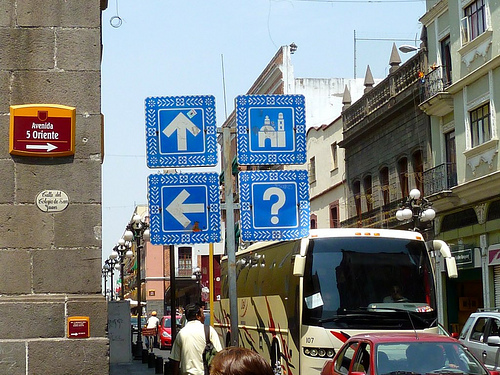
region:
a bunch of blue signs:
[142, 91, 317, 242]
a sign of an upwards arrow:
[142, 96, 224, 174]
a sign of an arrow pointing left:
[141, 171, 222, 245]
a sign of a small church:
[228, 105, 315, 170]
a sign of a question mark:
[237, 178, 308, 243]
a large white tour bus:
[220, 233, 444, 364]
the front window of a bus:
[327, 231, 447, 336]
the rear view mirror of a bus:
[425, 239, 465, 284]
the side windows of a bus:
[234, 251, 286, 293]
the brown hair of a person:
[201, 351, 268, 371]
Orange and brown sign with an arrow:
[7, 101, 78, 164]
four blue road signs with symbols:
[139, 93, 309, 250]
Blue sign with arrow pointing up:
[140, 93, 220, 170]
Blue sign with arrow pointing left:
[144, 171, 222, 246]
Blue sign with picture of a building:
[233, 93, 310, 169]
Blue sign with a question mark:
[235, 167, 310, 242]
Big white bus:
[215, 222, 449, 374]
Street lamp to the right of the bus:
[387, 183, 439, 232]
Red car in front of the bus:
[313, 318, 490, 374]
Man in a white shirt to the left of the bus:
[161, 296, 221, 373]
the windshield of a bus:
[304, 235, 441, 334]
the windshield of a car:
[374, 336, 481, 373]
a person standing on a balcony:
[410, 63, 453, 98]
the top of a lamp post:
[390, 186, 440, 226]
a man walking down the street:
[162, 302, 227, 374]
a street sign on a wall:
[3, 99, 83, 166]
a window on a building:
[462, 102, 496, 151]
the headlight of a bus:
[300, 344, 338, 364]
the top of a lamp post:
[123, 212, 153, 251]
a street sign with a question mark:
[235, 167, 313, 245]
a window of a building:
[467, 106, 482, 146]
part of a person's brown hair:
[201, 345, 272, 370]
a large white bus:
[212, 229, 438, 372]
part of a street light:
[123, 210, 157, 365]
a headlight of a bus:
[307, 343, 324, 358]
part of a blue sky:
[133, 0, 263, 75]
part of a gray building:
[5, 205, 102, 292]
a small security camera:
[396, 43, 421, 54]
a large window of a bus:
[304, 240, 431, 317]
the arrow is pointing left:
[134, 171, 218, 247]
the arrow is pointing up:
[134, 90, 220, 152]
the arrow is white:
[17, 127, 68, 164]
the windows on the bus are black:
[190, 230, 327, 338]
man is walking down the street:
[144, 298, 229, 363]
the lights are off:
[364, 153, 454, 232]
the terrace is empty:
[400, 127, 467, 208]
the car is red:
[316, 312, 491, 371]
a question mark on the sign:
[227, 167, 304, 234]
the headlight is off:
[292, 332, 344, 369]